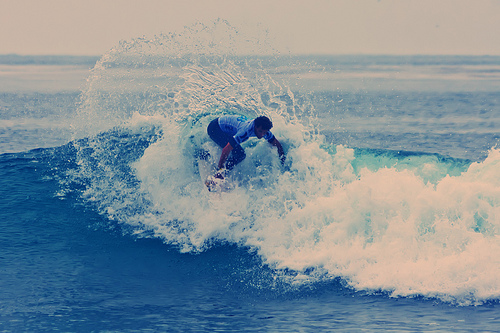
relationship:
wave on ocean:
[0, 18, 500, 309] [0, 48, 499, 331]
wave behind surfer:
[2, 72, 497, 309] [205, 114, 291, 178]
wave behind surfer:
[63, 120, 172, 188] [195, 100, 283, 190]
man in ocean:
[201, 110, 291, 181] [0, 48, 499, 331]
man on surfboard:
[203, 114, 287, 190] [185, 109, 299, 213]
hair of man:
[252, 115, 272, 129] [203, 114, 287, 190]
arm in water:
[254, 132, 292, 176] [0, 51, 498, 331]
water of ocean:
[0, 51, 498, 331] [0, 48, 499, 331]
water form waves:
[0, 51, 498, 331] [258, 126, 495, 309]